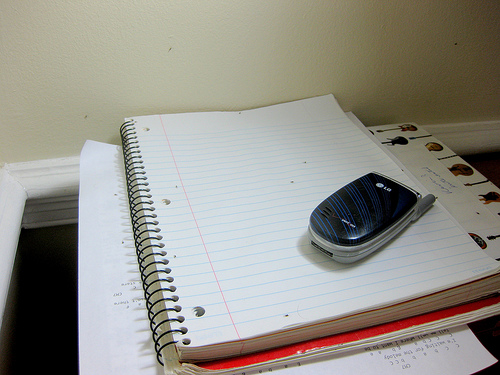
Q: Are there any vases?
A: No, there are no vases.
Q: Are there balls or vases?
A: No, there are no vases or balls.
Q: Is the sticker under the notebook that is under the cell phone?
A: Yes, the sticker is under the notebook.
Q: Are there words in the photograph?
A: Yes, there are words.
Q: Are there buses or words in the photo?
A: Yes, there are words.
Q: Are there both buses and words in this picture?
A: No, there are words but no buses.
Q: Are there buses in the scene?
A: No, there are no buses.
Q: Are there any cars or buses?
A: No, there are no buses or cars.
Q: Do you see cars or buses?
A: No, there are no buses or cars.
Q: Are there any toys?
A: No, there are no toys.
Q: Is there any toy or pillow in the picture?
A: No, there are no toys or pillows.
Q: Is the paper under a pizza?
A: No, the paper is under the notebook.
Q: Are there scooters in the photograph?
A: No, there are no scooters.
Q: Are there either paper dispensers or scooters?
A: No, there are no scooters or paper dispensers.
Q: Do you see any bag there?
A: No, there are no bags.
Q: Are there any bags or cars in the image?
A: No, there are no bags or cars.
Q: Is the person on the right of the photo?
A: Yes, the person is on the right of the image.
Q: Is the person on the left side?
A: No, the person is on the right of the image.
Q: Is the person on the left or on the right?
A: The person is on the right of the image.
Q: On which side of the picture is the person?
A: The person is on the right of the image.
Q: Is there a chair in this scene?
A: No, there are no chairs.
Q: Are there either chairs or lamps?
A: No, there are no chairs or lamps.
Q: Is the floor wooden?
A: Yes, the floor is wooden.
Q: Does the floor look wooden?
A: Yes, the floor is wooden.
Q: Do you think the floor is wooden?
A: Yes, the floor is wooden.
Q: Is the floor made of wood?
A: Yes, the floor is made of wood.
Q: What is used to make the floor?
A: The floor is made of wood.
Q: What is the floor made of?
A: The floor is made of wood.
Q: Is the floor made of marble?
A: No, the floor is made of wood.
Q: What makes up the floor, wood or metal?
A: The floor is made of wood.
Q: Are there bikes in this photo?
A: No, there are no bikes.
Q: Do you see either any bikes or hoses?
A: No, there are no bikes or hoses.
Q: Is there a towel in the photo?
A: No, there are no towels.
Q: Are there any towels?
A: No, there are no towels.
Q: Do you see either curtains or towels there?
A: No, there are no towels or curtains.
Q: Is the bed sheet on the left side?
A: Yes, the bed sheet is on the left of the image.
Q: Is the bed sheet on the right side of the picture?
A: No, the bed sheet is on the left of the image.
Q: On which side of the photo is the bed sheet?
A: The bed sheet is on the left of the image.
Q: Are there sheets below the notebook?
A: Yes, there is a sheet below the notebook.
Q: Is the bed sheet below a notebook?
A: Yes, the bed sheet is below a notebook.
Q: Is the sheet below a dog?
A: No, the sheet is below a notebook.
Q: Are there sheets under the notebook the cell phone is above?
A: Yes, there is a sheet under the notebook.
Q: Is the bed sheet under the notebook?
A: Yes, the bed sheet is under the notebook.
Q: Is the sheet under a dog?
A: No, the sheet is under the notebook.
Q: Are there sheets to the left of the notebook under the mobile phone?
A: Yes, there is a sheet to the left of the notebook.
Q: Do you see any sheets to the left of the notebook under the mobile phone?
A: Yes, there is a sheet to the left of the notebook.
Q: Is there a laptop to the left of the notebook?
A: No, there is a sheet to the left of the notebook.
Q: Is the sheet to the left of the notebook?
A: Yes, the sheet is to the left of the notebook.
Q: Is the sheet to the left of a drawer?
A: No, the sheet is to the left of the notebook.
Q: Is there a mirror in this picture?
A: No, there are no mirrors.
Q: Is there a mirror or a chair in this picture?
A: No, there are no mirrors or chairs.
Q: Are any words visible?
A: Yes, there are words.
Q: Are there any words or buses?
A: Yes, there are words.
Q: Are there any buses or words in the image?
A: Yes, there are words.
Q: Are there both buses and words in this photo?
A: No, there are words but no buses.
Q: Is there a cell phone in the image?
A: Yes, there is a cell phone.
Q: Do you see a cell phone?
A: Yes, there is a cell phone.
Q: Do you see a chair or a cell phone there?
A: Yes, there is a cell phone.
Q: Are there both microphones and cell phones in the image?
A: No, there is a cell phone but no microphones.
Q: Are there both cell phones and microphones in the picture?
A: No, there is a cell phone but no microphones.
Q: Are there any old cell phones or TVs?
A: Yes, there is an old cell phone.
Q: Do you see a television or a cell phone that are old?
A: Yes, the cell phone is old.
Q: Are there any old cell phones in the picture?
A: Yes, there is an old cell phone.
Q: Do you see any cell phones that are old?
A: Yes, there is a cell phone that is old.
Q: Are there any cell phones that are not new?
A: Yes, there is a old cell phone.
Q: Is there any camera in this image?
A: No, there are no cameras.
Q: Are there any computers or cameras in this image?
A: No, there are no cameras or computers.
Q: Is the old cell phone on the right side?
A: Yes, the cellphone is on the right of the image.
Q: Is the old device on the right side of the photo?
A: Yes, the cellphone is on the right of the image.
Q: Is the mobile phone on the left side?
A: No, the mobile phone is on the right of the image.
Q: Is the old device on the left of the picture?
A: No, the mobile phone is on the right of the image.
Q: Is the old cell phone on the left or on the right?
A: The mobile phone is on the right of the image.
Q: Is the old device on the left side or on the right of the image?
A: The mobile phone is on the right of the image.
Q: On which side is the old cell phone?
A: The cellphone is on the right of the image.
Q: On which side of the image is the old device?
A: The cellphone is on the right of the image.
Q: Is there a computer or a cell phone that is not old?
A: No, there is a cell phone but it is old.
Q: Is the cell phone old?
A: Yes, the cell phone is old.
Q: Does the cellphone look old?
A: Yes, the cellphone is old.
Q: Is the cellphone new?
A: No, the cellphone is old.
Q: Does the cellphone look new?
A: No, the cellphone is old.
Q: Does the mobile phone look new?
A: No, the mobile phone is old.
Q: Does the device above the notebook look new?
A: No, the mobile phone is old.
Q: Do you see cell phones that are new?
A: No, there is a cell phone but it is old.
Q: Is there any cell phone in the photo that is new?
A: No, there is a cell phone but it is old.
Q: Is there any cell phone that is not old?
A: No, there is a cell phone but it is old.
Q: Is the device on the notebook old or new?
A: The cellphone is old.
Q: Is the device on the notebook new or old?
A: The cellphone is old.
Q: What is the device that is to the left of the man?
A: The device is a cell phone.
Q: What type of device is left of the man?
A: The device is a cell phone.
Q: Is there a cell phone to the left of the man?
A: Yes, there is a cell phone to the left of the man.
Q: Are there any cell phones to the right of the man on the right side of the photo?
A: No, the cell phone is to the left of the man.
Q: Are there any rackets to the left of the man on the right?
A: No, there is a cell phone to the left of the man.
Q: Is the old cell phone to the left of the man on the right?
A: Yes, the cell phone is to the left of the man.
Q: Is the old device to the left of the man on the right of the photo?
A: Yes, the cell phone is to the left of the man.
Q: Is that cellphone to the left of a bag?
A: No, the cellphone is to the left of the man.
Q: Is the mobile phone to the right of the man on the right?
A: No, the mobile phone is to the left of the man.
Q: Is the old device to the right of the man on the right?
A: No, the mobile phone is to the left of the man.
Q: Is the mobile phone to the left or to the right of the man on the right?
A: The mobile phone is to the left of the man.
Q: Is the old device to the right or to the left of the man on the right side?
A: The mobile phone is to the left of the man.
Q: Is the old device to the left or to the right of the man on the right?
A: The mobile phone is to the left of the man.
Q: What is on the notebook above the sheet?
A: The mobile phone is on the notebook.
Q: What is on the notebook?
A: The mobile phone is on the notebook.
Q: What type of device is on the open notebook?
A: The device is a cell phone.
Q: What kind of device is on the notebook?
A: The device is a cell phone.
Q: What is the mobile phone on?
A: The mobile phone is on the notebook.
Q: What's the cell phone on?
A: The mobile phone is on the notebook.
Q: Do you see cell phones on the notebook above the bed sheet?
A: Yes, there is a cell phone on the notebook.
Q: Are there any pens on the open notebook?
A: No, there is a cell phone on the notebook.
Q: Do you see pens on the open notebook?
A: No, there is a cell phone on the notebook.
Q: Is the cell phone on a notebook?
A: Yes, the cell phone is on a notebook.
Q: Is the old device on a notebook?
A: Yes, the cell phone is on a notebook.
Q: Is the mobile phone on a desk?
A: No, the mobile phone is on a notebook.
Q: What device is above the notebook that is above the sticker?
A: The device is a cell phone.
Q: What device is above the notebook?
A: The device is a cell phone.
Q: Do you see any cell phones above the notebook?
A: Yes, there is a cell phone above the notebook.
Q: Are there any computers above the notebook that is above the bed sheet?
A: No, there is a cell phone above the notebook.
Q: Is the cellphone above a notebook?
A: Yes, the cellphone is above a notebook.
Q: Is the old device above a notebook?
A: Yes, the cellphone is above a notebook.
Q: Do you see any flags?
A: No, there are no flags.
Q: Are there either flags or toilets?
A: No, there are no flags or toilets.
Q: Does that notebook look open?
A: Yes, the notebook is open.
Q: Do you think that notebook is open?
A: Yes, the notebook is open.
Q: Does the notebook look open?
A: Yes, the notebook is open.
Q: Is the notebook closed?
A: No, the notebook is open.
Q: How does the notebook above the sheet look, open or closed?
A: The notebook is open.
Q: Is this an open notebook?
A: Yes, this is an open notebook.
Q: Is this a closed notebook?
A: No, this is an open notebook.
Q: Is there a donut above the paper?
A: No, there is a notebook above the paper.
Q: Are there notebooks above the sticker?
A: Yes, there is a notebook above the sticker.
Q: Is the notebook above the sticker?
A: Yes, the notebook is above the sticker.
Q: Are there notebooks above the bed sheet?
A: Yes, there is a notebook above the bed sheet.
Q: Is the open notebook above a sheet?
A: Yes, the notebook is above a sheet.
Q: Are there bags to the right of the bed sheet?
A: No, there is a notebook to the right of the bed sheet.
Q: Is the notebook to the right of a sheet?
A: Yes, the notebook is to the right of a sheet.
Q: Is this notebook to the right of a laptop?
A: No, the notebook is to the right of a sheet.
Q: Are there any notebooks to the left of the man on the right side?
A: Yes, there is a notebook to the left of the man.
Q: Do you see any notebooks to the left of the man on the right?
A: Yes, there is a notebook to the left of the man.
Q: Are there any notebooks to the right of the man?
A: No, the notebook is to the left of the man.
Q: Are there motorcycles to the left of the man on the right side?
A: No, there is a notebook to the left of the man.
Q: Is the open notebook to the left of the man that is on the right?
A: Yes, the notebook is to the left of the man.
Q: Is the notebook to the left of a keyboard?
A: No, the notebook is to the left of the man.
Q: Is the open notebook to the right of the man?
A: No, the notebook is to the left of the man.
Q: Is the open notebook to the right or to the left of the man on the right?
A: The notebook is to the left of the man.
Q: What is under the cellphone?
A: The notebook is under the cellphone.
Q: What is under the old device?
A: The notebook is under the cellphone.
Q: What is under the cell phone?
A: The notebook is under the cellphone.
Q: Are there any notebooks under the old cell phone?
A: Yes, there is a notebook under the mobile phone.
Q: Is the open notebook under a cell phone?
A: Yes, the notebook is under a cell phone.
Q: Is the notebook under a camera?
A: No, the notebook is under a cell phone.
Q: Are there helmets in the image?
A: No, there are no helmets.